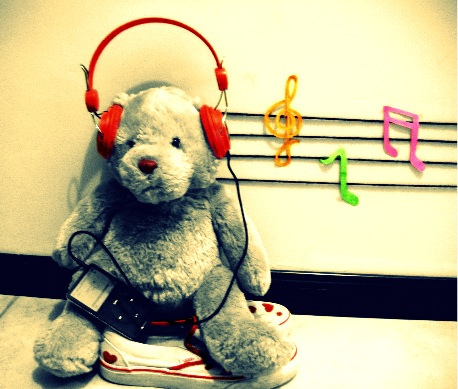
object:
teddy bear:
[34, 86, 292, 380]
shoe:
[100, 351, 117, 364]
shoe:
[99, 331, 299, 387]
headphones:
[79, 17, 231, 160]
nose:
[138, 158, 158, 174]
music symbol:
[263, 75, 303, 167]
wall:
[0, 0, 458, 279]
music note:
[319, 148, 359, 206]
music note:
[382, 103, 426, 172]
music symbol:
[264, 74, 426, 206]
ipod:
[67, 263, 156, 344]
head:
[108, 87, 220, 205]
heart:
[103, 351, 118, 364]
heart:
[262, 303, 275, 313]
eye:
[125, 138, 135, 147]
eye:
[172, 138, 180, 148]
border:
[0, 253, 456, 322]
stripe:
[97, 359, 243, 381]